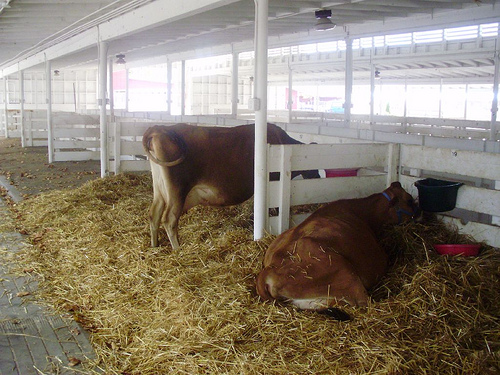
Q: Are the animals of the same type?
A: Yes, all the animals are cows.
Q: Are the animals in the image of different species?
A: No, all the animals are cows.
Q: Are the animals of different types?
A: No, all the animals are cows.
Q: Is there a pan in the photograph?
A: Yes, there is a pan.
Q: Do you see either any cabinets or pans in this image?
A: Yes, there is a pan.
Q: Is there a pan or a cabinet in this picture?
A: Yes, there is a pan.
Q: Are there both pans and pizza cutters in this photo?
A: No, there is a pan but no pizza cutters.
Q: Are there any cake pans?
A: No, there are no cake pans.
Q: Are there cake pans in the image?
A: No, there are no cake pans.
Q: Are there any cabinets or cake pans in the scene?
A: No, there are no cake pans or cabinets.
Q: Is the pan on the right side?
A: Yes, the pan is on the right of the image.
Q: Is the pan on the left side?
A: No, the pan is on the right of the image.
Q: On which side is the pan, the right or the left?
A: The pan is on the right of the image.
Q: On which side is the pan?
A: The pan is on the right of the image.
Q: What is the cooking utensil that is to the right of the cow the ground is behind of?
A: The cooking utensil is a pan.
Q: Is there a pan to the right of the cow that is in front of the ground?
A: Yes, there is a pan to the right of the cow.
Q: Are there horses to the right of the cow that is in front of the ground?
A: No, there is a pan to the right of the cow.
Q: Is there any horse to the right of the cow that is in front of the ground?
A: No, there is a pan to the right of the cow.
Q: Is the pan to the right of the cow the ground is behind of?
A: Yes, the pan is to the right of the cow.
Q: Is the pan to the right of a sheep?
A: No, the pan is to the right of the cow.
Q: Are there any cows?
A: Yes, there is a cow.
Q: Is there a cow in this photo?
A: Yes, there is a cow.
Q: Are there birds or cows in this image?
A: Yes, there is a cow.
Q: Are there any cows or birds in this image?
A: Yes, there is a cow.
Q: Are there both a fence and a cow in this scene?
A: Yes, there are both a cow and a fence.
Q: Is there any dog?
A: No, there are no dogs.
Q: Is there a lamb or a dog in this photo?
A: No, there are no dogs or lambs.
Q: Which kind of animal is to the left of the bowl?
A: The animal is a cow.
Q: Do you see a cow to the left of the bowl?
A: Yes, there is a cow to the left of the bowl.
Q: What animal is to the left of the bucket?
A: The animal is a cow.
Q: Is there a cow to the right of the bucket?
A: No, the cow is to the left of the bucket.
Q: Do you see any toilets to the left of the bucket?
A: No, there is a cow to the left of the bucket.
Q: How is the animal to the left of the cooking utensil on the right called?
A: The animal is a cow.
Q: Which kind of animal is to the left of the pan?
A: The animal is a cow.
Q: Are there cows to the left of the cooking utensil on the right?
A: Yes, there is a cow to the left of the pan.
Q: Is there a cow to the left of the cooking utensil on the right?
A: Yes, there is a cow to the left of the pan.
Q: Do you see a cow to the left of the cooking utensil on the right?
A: Yes, there is a cow to the left of the pan.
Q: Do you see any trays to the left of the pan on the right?
A: No, there is a cow to the left of the pan.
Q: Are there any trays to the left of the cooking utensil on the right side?
A: No, there is a cow to the left of the pan.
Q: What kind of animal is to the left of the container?
A: The animal is a cow.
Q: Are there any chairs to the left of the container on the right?
A: No, there is a cow to the left of the container.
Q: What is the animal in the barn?
A: The animal is a cow.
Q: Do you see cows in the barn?
A: Yes, there is a cow in the barn.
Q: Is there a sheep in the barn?
A: No, there is a cow in the barn.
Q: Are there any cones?
A: No, there are no cones.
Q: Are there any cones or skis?
A: No, there are no cones or skis.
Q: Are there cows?
A: Yes, there is a cow.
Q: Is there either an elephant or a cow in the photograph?
A: Yes, there is a cow.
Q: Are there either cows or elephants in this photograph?
A: Yes, there is a cow.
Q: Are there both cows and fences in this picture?
A: Yes, there are both a cow and a fence.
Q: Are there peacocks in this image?
A: No, there are no peacocks.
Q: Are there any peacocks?
A: No, there are no peacocks.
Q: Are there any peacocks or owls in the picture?
A: No, there are no peacocks or owls.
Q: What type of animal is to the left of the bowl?
A: The animal is a cow.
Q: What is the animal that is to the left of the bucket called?
A: The animal is a cow.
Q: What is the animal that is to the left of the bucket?
A: The animal is a cow.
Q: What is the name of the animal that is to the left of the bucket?
A: The animal is a cow.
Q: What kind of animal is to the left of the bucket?
A: The animal is a cow.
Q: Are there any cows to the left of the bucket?
A: Yes, there is a cow to the left of the bucket.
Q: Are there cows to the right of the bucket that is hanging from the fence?
A: No, the cow is to the left of the bucket.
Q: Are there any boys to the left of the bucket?
A: No, there is a cow to the left of the bucket.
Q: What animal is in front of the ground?
A: The cow is in front of the ground.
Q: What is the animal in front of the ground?
A: The animal is a cow.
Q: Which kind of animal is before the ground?
A: The animal is a cow.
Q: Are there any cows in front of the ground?
A: Yes, there is a cow in front of the ground.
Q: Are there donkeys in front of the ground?
A: No, there is a cow in front of the ground.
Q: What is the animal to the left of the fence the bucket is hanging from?
A: The animal is a cow.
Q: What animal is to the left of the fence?
A: The animal is a cow.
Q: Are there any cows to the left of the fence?
A: Yes, there is a cow to the left of the fence.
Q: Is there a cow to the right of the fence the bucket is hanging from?
A: No, the cow is to the left of the fence.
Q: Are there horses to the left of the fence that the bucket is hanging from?
A: No, there is a cow to the left of the fence.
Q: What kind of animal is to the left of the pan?
A: The animal is a cow.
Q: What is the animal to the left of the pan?
A: The animal is a cow.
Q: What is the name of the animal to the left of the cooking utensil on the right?
A: The animal is a cow.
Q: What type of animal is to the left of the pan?
A: The animal is a cow.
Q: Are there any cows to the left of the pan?
A: Yes, there is a cow to the left of the pan.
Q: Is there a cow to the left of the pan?
A: Yes, there is a cow to the left of the pan.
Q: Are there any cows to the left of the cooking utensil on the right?
A: Yes, there is a cow to the left of the pan.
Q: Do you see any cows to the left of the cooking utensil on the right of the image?
A: Yes, there is a cow to the left of the pan.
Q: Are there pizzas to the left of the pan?
A: No, there is a cow to the left of the pan.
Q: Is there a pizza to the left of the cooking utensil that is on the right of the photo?
A: No, there is a cow to the left of the pan.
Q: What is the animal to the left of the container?
A: The animal is a cow.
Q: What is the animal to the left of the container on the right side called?
A: The animal is a cow.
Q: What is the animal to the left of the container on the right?
A: The animal is a cow.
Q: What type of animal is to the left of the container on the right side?
A: The animal is a cow.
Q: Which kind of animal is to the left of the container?
A: The animal is a cow.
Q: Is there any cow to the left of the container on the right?
A: Yes, there is a cow to the left of the container.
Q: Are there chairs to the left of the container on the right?
A: No, there is a cow to the left of the container.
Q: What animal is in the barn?
A: The cow is in the barn.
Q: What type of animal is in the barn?
A: The animal is a cow.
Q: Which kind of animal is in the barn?
A: The animal is a cow.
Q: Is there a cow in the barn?
A: Yes, there is a cow in the barn.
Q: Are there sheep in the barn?
A: No, there is a cow in the barn.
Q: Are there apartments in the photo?
A: No, there are no apartments.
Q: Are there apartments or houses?
A: No, there are no apartments or houses.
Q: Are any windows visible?
A: Yes, there is a window.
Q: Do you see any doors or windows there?
A: Yes, there is a window.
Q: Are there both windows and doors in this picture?
A: No, there is a window but no doors.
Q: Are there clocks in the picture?
A: No, there are no clocks.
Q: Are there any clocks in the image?
A: No, there are no clocks.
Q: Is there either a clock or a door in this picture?
A: No, there are no clocks or doors.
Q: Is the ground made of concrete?
A: Yes, the ground is made of concrete.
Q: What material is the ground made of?
A: The ground is made of cement.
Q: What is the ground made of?
A: The ground is made of concrete.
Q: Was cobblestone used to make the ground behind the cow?
A: No, the ground is made of cement.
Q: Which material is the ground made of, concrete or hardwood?
A: The ground is made of concrete.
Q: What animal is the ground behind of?
A: The ground is behind the cow.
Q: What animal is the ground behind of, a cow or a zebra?
A: The ground is behind a cow.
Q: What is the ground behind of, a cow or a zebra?
A: The ground is behind a cow.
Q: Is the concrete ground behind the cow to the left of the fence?
A: Yes, the ground is behind the cow.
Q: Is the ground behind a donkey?
A: No, the ground is behind the cow.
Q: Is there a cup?
A: No, there are no cups.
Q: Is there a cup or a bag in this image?
A: No, there are no cups or bags.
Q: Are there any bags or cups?
A: No, there are no cups or bags.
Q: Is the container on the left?
A: No, the container is on the right of the image.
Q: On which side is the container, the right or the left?
A: The container is on the right of the image.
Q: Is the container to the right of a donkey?
A: No, the container is to the right of a cow.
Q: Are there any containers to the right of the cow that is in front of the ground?
A: Yes, there is a container to the right of the cow.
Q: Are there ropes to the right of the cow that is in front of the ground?
A: No, there is a container to the right of the cow.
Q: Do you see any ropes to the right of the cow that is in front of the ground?
A: No, there is a container to the right of the cow.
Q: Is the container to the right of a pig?
A: No, the container is to the right of the cow.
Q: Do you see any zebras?
A: No, there are no zebras.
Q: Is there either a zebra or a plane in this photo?
A: No, there are no zebras or airplanes.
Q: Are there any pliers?
A: No, there are no pliers.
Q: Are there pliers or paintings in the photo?
A: No, there are no pliers or paintings.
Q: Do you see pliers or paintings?
A: No, there are no pliers or paintings.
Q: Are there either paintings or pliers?
A: No, there are no pliers or paintings.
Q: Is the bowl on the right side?
A: Yes, the bowl is on the right of the image.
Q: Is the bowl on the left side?
A: No, the bowl is on the right of the image.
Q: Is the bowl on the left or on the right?
A: The bowl is on the right of the image.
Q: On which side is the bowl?
A: The bowl is on the right of the image.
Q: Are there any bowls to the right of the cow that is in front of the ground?
A: Yes, there is a bowl to the right of the cow.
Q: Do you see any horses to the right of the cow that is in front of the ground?
A: No, there is a bowl to the right of the cow.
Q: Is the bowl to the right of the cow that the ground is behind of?
A: Yes, the bowl is to the right of the cow.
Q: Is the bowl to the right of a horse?
A: No, the bowl is to the right of the cow.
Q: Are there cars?
A: No, there are no cars.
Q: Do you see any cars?
A: No, there are no cars.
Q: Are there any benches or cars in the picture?
A: No, there are no cars or benches.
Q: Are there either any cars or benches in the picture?
A: No, there are no cars or benches.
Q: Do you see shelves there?
A: No, there are no shelves.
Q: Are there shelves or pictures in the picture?
A: No, there are no shelves or pictures.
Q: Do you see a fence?
A: Yes, there is a fence.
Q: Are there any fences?
A: Yes, there is a fence.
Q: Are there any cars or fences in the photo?
A: Yes, there is a fence.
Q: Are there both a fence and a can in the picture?
A: No, there is a fence but no cans.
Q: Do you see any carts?
A: No, there are no carts.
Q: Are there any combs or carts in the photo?
A: No, there are no carts or combs.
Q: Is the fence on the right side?
A: Yes, the fence is on the right of the image.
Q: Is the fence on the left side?
A: No, the fence is on the right of the image.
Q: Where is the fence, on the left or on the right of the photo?
A: The fence is on the right of the image.